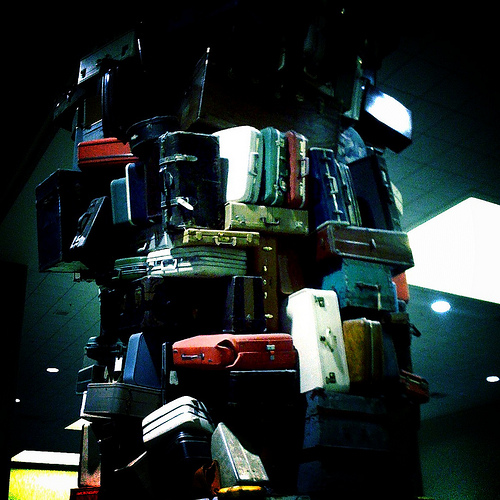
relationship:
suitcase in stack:
[53, 34, 459, 475] [46, 10, 454, 490]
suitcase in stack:
[53, 34, 459, 475] [28, 5, 433, 495]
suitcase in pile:
[53, 34, 459, 475] [28, 10, 433, 487]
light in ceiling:
[425, 292, 452, 321] [366, 183, 495, 308]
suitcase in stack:
[53, 34, 459, 475] [137, 79, 491, 411]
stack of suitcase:
[137, 79, 491, 411] [53, 34, 459, 475]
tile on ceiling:
[425, 64, 499, 136] [387, 132, 499, 257]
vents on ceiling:
[7, 297, 83, 392] [387, 132, 499, 257]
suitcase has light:
[53, 34, 459, 475] [366, 183, 495, 308]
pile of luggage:
[137, 79, 491, 411] [97, 298, 210, 397]